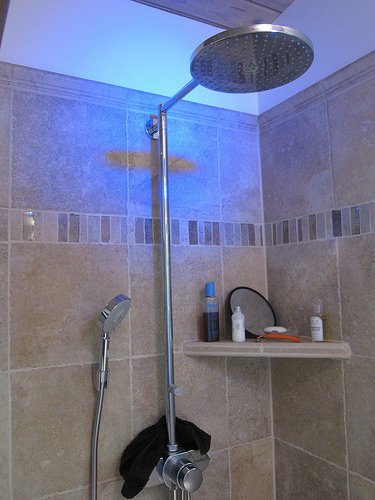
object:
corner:
[223, 16, 292, 128]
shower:
[5, 4, 364, 392]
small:
[70, 290, 150, 352]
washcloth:
[89, 402, 227, 493]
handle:
[141, 418, 218, 499]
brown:
[10, 88, 135, 222]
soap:
[222, 304, 254, 348]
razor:
[251, 328, 316, 351]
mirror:
[225, 282, 285, 342]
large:
[148, 23, 332, 126]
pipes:
[147, 153, 195, 451]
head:
[192, 23, 317, 109]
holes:
[254, 32, 260, 41]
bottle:
[201, 279, 220, 344]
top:
[201, 281, 220, 300]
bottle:
[231, 306, 249, 343]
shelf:
[196, 328, 365, 362]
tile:
[11, 85, 134, 219]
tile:
[12, 66, 136, 119]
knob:
[155, 447, 218, 493]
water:
[39, 16, 347, 493]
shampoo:
[203, 279, 224, 343]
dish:
[256, 322, 299, 343]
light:
[126, 0, 303, 27]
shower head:
[101, 294, 131, 395]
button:
[172, 466, 207, 496]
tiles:
[175, 218, 270, 251]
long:
[151, 105, 186, 396]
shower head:
[95, 293, 134, 360]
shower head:
[189, 23, 319, 100]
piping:
[144, 101, 192, 451]